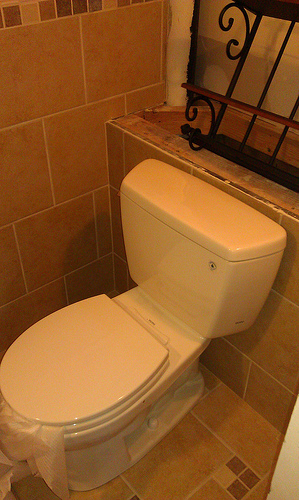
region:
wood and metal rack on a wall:
[185, 0, 298, 178]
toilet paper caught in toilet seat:
[0, 387, 67, 498]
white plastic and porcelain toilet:
[0, 153, 287, 490]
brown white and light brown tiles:
[194, 413, 258, 499]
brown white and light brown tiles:
[0, 1, 165, 103]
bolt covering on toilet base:
[147, 415, 159, 429]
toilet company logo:
[206, 259, 217, 270]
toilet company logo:
[145, 317, 156, 324]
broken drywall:
[168, 2, 180, 102]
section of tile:
[118, 476, 267, 497]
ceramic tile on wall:
[17, 223, 100, 275]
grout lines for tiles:
[42, 136, 61, 197]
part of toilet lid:
[122, 181, 249, 204]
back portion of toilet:
[133, 219, 176, 296]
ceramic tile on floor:
[214, 458, 262, 490]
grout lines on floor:
[188, 413, 217, 434]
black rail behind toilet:
[223, 6, 272, 68]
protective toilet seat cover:
[5, 406, 54, 474]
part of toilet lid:
[8, 327, 125, 387]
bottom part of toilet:
[73, 454, 122, 476]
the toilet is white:
[14, 273, 144, 440]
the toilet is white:
[46, 181, 280, 445]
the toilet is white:
[19, 150, 243, 364]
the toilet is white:
[18, 261, 235, 466]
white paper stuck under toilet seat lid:
[1, 387, 75, 494]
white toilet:
[2, 156, 279, 488]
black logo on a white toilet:
[206, 259, 218, 271]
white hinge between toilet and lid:
[119, 299, 171, 348]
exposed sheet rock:
[197, 1, 298, 104]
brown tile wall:
[1, 37, 116, 314]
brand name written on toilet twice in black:
[142, 316, 250, 330]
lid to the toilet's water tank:
[120, 151, 292, 262]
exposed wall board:
[113, 117, 297, 206]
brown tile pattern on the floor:
[197, 383, 293, 497]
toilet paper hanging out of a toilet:
[1, 417, 76, 497]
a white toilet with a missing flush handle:
[6, 159, 286, 489]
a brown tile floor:
[65, 433, 277, 498]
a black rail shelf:
[180, 1, 298, 170]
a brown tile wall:
[11, 159, 116, 316]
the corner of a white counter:
[263, 392, 293, 494]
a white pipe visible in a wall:
[156, 1, 195, 106]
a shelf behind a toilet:
[121, 96, 293, 172]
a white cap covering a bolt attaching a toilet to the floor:
[143, 414, 161, 431]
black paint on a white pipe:
[186, 2, 200, 105]